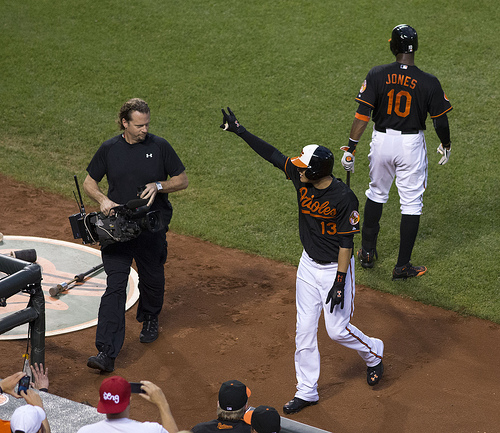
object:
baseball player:
[220, 105, 385, 415]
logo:
[298, 187, 337, 218]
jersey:
[236, 127, 361, 262]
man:
[219, 107, 385, 415]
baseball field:
[0, 0, 499, 325]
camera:
[130, 382, 145, 392]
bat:
[344, 154, 350, 187]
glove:
[434, 143, 453, 165]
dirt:
[203, 289, 264, 336]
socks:
[394, 213, 420, 266]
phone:
[128, 382, 145, 394]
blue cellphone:
[15, 374, 32, 395]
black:
[17, 384, 28, 389]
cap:
[389, 24, 419, 55]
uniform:
[219, 109, 401, 406]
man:
[75, 376, 178, 432]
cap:
[97, 374, 132, 413]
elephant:
[385, 72, 418, 117]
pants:
[281, 249, 384, 414]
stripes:
[344, 260, 384, 361]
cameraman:
[82, 98, 190, 373]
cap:
[288, 143, 335, 182]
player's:
[186, 379, 251, 433]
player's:
[238, 406, 290, 433]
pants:
[364, 129, 430, 216]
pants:
[94, 232, 169, 357]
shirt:
[352, 61, 455, 132]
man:
[340, 24, 454, 279]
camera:
[67, 174, 166, 250]